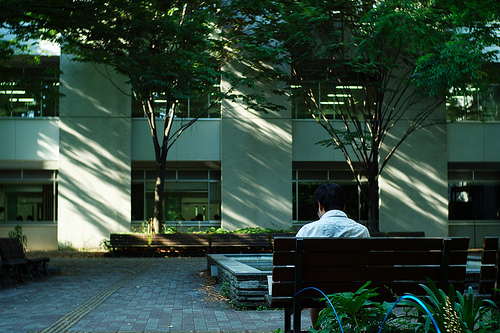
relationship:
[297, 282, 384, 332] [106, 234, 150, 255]
plant on bench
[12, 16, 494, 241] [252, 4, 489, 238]
wall surrounds tree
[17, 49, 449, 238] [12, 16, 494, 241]
sun on wall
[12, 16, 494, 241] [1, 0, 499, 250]
wall on building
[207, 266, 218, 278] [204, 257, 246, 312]
box on stone wall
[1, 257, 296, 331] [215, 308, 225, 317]
pavement has brick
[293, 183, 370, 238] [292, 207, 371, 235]
man has on white shirt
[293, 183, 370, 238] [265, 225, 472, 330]
man sitting on bench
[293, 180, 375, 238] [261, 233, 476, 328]
man sitting on bench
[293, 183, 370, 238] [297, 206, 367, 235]
man wearing shirt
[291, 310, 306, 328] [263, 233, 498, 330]
leg of bench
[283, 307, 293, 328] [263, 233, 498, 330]
leg of bench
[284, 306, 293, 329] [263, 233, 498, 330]
front leg of bench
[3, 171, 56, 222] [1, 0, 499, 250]
windows on building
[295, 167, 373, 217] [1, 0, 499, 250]
windows on building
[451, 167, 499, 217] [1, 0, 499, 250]
windows on building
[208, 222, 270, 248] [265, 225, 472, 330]
bench on bench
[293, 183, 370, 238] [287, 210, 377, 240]
man wearing t-shirt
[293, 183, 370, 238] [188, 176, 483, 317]
man sitting bench